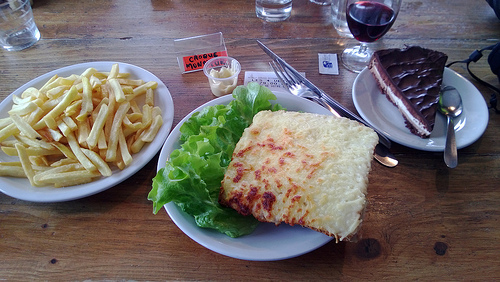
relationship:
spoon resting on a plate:
[437, 85, 464, 168] [348, 56, 491, 151]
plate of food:
[156, 92, 337, 262] [157, 88, 349, 262]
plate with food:
[10, 58, 175, 200] [363, 47, 444, 136]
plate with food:
[341, 44, 493, 156] [239, 103, 370, 231]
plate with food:
[168, 84, 368, 261] [15, 88, 143, 176]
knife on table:
[250, 34, 390, 146] [10, 4, 499, 265]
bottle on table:
[5, 4, 42, 51] [7, 6, 192, 83]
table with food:
[6, 204, 161, 277] [0, 59, 159, 176]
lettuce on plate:
[145, 81, 292, 239] [147, 80, 357, 265]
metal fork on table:
[250, 38, 403, 166] [10, 4, 499, 265]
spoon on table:
[440, 84, 464, 174] [10, 4, 499, 265]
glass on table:
[341, 1, 397, 75] [3, 9, 490, 280]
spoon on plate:
[437, 85, 464, 168] [351, 62, 490, 152]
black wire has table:
[444, 33, 491, 78] [0, 0, 499, 282]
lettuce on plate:
[145, 177, 190, 217] [212, 237, 298, 264]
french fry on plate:
[33, 163, 98, 187] [72, 180, 100, 214]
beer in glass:
[342, 4, 398, 44] [343, 2, 401, 72]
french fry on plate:
[27, 169, 96, 184] [10, 58, 175, 200]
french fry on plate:
[105, 76, 125, 104] [10, 58, 175, 200]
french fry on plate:
[6, 110, 43, 140] [10, 58, 175, 200]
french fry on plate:
[85, 100, 109, 147] [10, 58, 175, 200]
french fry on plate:
[35, 84, 76, 127] [10, 58, 175, 200]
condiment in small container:
[208, 64, 238, 97] [200, 52, 245, 95]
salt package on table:
[315, 50, 341, 77] [10, 4, 499, 265]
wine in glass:
[345, 4, 397, 44] [343, 3, 398, 40]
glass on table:
[343, 3, 398, 40] [10, 4, 499, 265]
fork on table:
[268, 52, 400, 171] [10, 4, 499, 265]